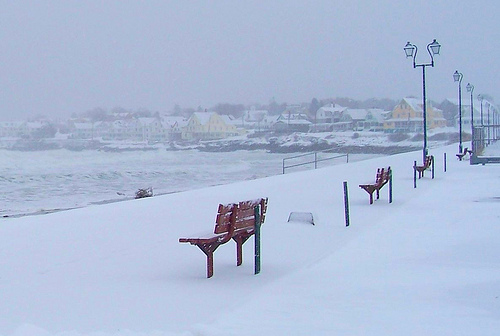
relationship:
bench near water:
[179, 192, 271, 283] [0, 145, 398, 217]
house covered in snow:
[389, 93, 438, 129] [403, 96, 433, 113]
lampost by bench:
[397, 28, 443, 166] [411, 154, 441, 180]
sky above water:
[3, 5, 494, 119] [0, 145, 398, 217]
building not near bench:
[311, 101, 357, 131] [179, 192, 271, 283]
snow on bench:
[181, 232, 227, 244] [179, 192, 271, 283]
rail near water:
[280, 148, 361, 176] [0, 145, 398, 217]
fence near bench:
[468, 125, 500, 167] [179, 192, 271, 283]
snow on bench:
[403, 96, 433, 113] [179, 192, 271, 283]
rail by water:
[280, 148, 361, 176] [0, 145, 398, 217]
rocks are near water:
[262, 137, 383, 158] [0, 145, 398, 217]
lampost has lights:
[397, 28, 443, 166] [399, 35, 450, 59]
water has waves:
[0, 145, 398, 217] [10, 161, 174, 184]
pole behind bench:
[386, 165, 396, 202] [361, 164, 394, 211]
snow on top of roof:
[403, 96, 433, 113] [396, 92, 441, 118]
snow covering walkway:
[6, 218, 94, 335] [1, 184, 231, 261]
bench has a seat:
[179, 192, 271, 283] [177, 223, 265, 247]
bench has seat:
[179, 192, 271, 283] [177, 223, 265, 247]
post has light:
[455, 82, 469, 166] [450, 67, 465, 86]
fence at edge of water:
[468, 125, 500, 167] [0, 145, 398, 217]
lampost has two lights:
[397, 28, 443, 166] [399, 35, 450, 59]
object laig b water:
[134, 186, 156, 203] [0, 145, 398, 217]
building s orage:
[311, 101, 357, 131] [394, 103, 431, 125]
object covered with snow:
[134, 186, 156, 203] [6, 218, 94, 335]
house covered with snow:
[389, 93, 438, 129] [6, 218, 94, 335]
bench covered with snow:
[179, 192, 271, 283] [6, 218, 94, 335]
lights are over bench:
[399, 35, 450, 59] [409, 154, 451, 190]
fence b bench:
[468, 125, 500, 167] [409, 154, 451, 190]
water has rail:
[0, 145, 398, 217] [280, 148, 361, 176]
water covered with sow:
[0, 145, 398, 217] [10, 161, 174, 184]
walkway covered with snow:
[1, 184, 231, 261] [6, 218, 94, 335]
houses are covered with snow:
[249, 100, 484, 137] [6, 218, 94, 335]